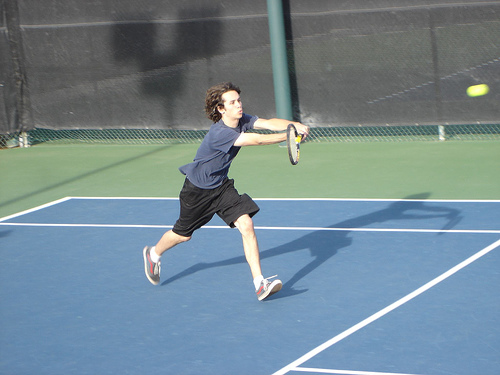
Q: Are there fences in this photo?
A: Yes, there is a fence.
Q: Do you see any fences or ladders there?
A: Yes, there is a fence.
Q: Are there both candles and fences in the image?
A: No, there is a fence but no candles.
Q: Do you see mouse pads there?
A: No, there are no mouse pads.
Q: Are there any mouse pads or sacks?
A: No, there are no mouse pads or sacks.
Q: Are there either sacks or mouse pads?
A: No, there are no mouse pads or sacks.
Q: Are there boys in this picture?
A: No, there are no boys.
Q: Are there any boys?
A: No, there are no boys.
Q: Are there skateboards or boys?
A: No, there are no boys or skateboards.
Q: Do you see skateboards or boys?
A: No, there are no boys or skateboards.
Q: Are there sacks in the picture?
A: No, there are no sacks.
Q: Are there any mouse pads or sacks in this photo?
A: No, there are no sacks or mouse pads.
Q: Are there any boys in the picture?
A: No, there are no boys.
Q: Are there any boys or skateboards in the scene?
A: No, there are no boys or skateboards.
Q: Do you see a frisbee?
A: No, there are no frisbees.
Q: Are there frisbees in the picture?
A: No, there are no frisbees.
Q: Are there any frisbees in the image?
A: No, there are no frisbees.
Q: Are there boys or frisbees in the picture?
A: No, there are no frisbees or boys.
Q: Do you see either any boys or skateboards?
A: No, there are no skateboards or boys.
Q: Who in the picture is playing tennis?
A: The man is playing tennis.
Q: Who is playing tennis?
A: The man is playing tennis.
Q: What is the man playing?
A: The man is playing tennis.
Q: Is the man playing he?
A: Yes, the man is playing tennis.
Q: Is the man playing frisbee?
A: No, the man is playing tennis.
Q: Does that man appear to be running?
A: Yes, the man is running.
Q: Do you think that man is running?
A: Yes, the man is running.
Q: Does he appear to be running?
A: Yes, the man is running.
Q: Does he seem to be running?
A: Yes, the man is running.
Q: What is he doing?
A: The man is running.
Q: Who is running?
A: The man is running.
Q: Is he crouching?
A: No, the man is running.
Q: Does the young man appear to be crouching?
A: No, the man is running.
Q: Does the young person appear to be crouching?
A: No, the man is running.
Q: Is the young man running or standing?
A: The man is running.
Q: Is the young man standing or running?
A: The man is running.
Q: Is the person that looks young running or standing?
A: The man is running.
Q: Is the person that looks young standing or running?
A: The man is running.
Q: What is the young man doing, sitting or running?
A: The man is running.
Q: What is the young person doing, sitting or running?
A: The man is running.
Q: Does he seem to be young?
A: Yes, the man is young.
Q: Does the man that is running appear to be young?
A: Yes, the man is young.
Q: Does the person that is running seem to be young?
A: Yes, the man is young.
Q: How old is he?
A: The man is young.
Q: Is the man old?
A: No, the man is young.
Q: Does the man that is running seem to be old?
A: No, the man is young.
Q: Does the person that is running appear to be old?
A: No, the man is young.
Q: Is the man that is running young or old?
A: The man is young.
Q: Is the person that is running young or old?
A: The man is young.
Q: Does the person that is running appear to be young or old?
A: The man is young.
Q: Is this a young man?
A: Yes, this is a young man.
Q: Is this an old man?
A: No, this is a young man.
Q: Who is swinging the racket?
A: The man is swinging the racket.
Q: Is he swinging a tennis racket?
A: Yes, the man is swinging a tennis racket.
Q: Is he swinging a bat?
A: No, the man is swinging a tennis racket.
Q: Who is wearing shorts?
A: The man is wearing shorts.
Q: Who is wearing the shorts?
A: The man is wearing shorts.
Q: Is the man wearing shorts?
A: Yes, the man is wearing shorts.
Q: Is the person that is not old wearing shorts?
A: Yes, the man is wearing shorts.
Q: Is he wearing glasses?
A: No, the man is wearing shorts.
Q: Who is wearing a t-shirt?
A: The man is wearing a t-shirt.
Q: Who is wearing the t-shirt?
A: The man is wearing a t-shirt.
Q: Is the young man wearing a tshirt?
A: Yes, the man is wearing a tshirt.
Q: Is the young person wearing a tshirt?
A: Yes, the man is wearing a tshirt.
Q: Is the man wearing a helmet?
A: No, the man is wearing a tshirt.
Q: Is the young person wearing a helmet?
A: No, the man is wearing a tshirt.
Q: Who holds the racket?
A: The man holds the racket.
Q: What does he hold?
A: The man holds the racket.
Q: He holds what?
A: The man holds the racket.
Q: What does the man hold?
A: The man holds the racket.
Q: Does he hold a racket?
A: Yes, the man holds a racket.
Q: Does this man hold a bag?
A: No, the man holds a racket.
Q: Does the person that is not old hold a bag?
A: No, the man holds a racket.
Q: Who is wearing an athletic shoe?
A: The man is wearing an athletic shoe.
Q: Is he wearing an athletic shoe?
A: Yes, the man is wearing an athletic shoe.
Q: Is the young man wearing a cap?
A: No, the man is wearing an athletic shoe.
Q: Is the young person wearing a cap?
A: No, the man is wearing an athletic shoe.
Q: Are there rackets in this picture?
A: Yes, there is a racket.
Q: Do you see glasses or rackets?
A: Yes, there is a racket.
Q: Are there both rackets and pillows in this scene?
A: No, there is a racket but no pillows.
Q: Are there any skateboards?
A: No, there are no skateboards.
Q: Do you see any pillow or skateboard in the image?
A: No, there are no skateboards or pillows.